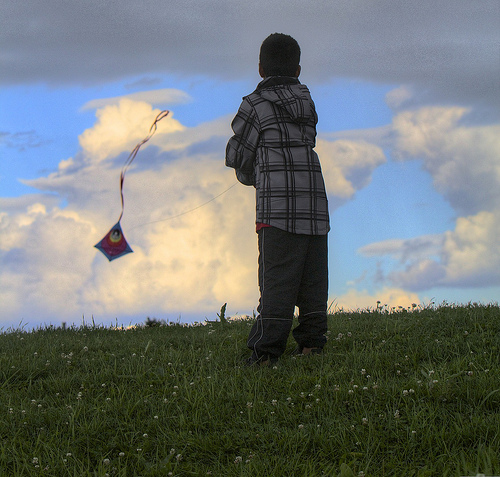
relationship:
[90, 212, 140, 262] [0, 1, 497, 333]
kite in sky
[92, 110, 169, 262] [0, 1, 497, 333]
kite flying in sky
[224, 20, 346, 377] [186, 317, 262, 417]
boy standing in grass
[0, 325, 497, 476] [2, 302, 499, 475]
flowers in grass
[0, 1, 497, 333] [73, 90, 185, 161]
sky full of cloud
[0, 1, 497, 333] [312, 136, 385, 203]
sky full of cloud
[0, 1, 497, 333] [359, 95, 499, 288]
sky full of cloud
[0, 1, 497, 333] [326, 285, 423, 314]
sky full of cloud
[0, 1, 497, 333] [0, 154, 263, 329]
sky full of cloud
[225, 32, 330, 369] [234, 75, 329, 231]
boy wearing hoodie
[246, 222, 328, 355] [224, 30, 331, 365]
jeans on boy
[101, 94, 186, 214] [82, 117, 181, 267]
strings on kite